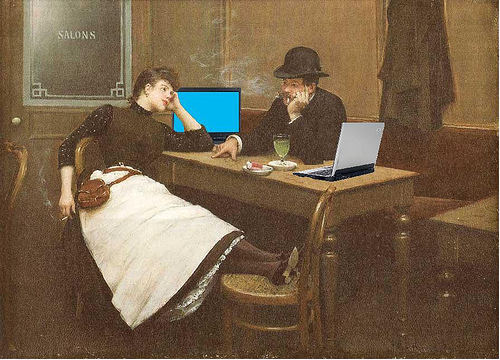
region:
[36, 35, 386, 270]
this is a vintage photo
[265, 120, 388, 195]
these are laptops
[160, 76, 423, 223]
the laptops are out of place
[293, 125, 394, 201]
the laptop is silver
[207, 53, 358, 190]
the man has a hat on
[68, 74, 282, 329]
the woman has a long dress on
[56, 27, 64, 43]
white letter on wall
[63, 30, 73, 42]
white letter on wall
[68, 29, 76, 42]
white letter on wall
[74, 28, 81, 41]
white letter on wall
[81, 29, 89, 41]
white letter on wall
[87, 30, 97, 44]
white letter on wall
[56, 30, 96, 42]
white letters on wall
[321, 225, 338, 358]
brown wooden table leg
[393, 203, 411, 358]
brown wooden table leg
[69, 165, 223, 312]
the skirt is white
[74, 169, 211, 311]
the skirt is white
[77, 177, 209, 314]
the skirt is white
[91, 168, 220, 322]
the skirt is white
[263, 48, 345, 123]
man wearing a hat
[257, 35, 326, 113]
man wearing a hat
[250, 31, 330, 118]
man wearing a hat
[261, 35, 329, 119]
man wearing a hat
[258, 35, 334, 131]
man wearing a hat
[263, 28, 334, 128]
man wearing a hat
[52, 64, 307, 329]
The painting has a woman in it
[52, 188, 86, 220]
the woman is smoking a cigarette.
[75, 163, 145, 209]
The woman has a brown purse.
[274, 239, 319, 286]
The woman is wearing black heels.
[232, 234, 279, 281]
The woman is wearing black stockings.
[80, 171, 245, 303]
The woman has on a white skirt.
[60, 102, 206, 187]
The woman is wearing a black shirt.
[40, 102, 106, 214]
The left hand of the woman.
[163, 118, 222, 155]
The right hand of the woman.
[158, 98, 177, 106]
The lips of the woman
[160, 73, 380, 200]
laptops on the table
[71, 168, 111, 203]
the bag is brown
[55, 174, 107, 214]
the bag is brown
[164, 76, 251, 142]
the screen is blue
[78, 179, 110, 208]
Brown purse on a woman.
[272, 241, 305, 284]
A womans black shoes.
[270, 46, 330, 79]
A black hat on a man.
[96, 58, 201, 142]
head of a lady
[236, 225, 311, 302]
feet of the lady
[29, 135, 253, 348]
dress on the lady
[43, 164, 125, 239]
purse on the lady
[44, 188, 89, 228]
hand of the lady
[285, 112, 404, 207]
laptop on the table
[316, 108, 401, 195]
back of the laptop